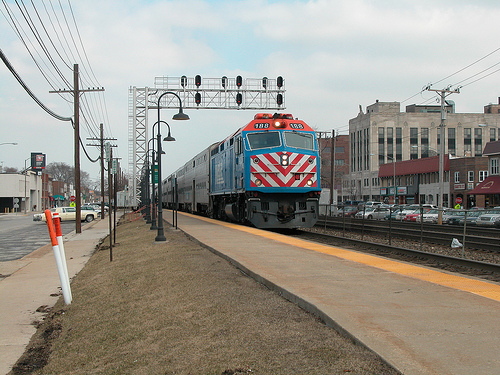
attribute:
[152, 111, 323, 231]
train — blue , red , white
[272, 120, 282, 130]
headlight — white, bright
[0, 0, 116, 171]
wires — long 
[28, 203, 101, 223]
car — tan, long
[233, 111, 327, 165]
window — train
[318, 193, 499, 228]
cars — parked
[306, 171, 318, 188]
headlight — bright, white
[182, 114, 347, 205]
train — red, white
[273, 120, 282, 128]
headlight — bright